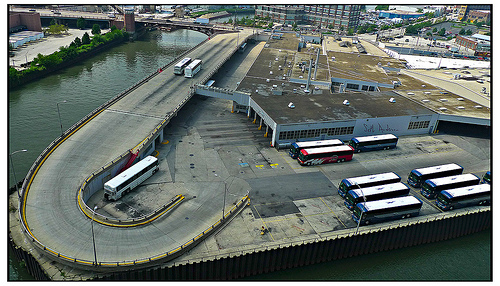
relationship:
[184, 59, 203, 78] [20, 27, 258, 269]
bus on road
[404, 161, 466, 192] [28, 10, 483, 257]
bus on road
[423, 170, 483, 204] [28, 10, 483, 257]
bus on road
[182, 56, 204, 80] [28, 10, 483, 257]
bus on road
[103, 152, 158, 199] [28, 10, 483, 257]
bus on road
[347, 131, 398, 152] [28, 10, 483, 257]
bus on road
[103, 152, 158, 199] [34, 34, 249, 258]
bus on road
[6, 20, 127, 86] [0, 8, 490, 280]
trees in photo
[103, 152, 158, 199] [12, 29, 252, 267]
bus near bridge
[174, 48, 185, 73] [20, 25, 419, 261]
bus driving on highway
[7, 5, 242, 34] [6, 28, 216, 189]
bridge across river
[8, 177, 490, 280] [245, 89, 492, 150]
fence around building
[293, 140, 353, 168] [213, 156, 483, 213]
bus parked in parking lot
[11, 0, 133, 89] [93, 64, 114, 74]
bushes next to water